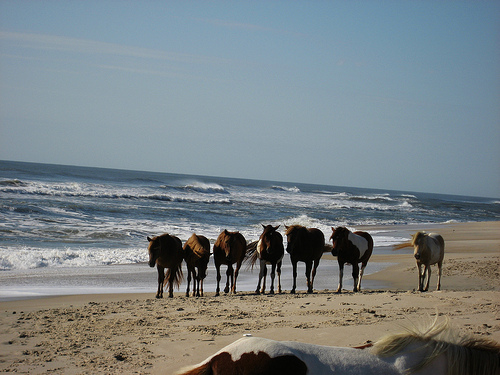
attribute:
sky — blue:
[158, 32, 316, 118]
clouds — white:
[189, 40, 259, 113]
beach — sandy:
[114, 301, 397, 342]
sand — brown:
[175, 298, 289, 338]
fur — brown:
[226, 232, 251, 254]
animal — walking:
[130, 199, 440, 309]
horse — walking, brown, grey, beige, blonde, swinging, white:
[369, 205, 465, 287]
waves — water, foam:
[44, 161, 218, 218]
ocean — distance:
[4, 119, 328, 246]